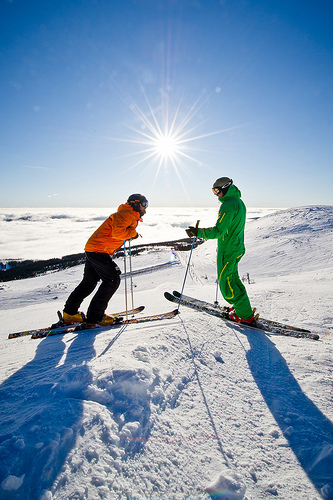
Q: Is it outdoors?
A: Yes, it is outdoors.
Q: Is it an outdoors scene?
A: Yes, it is outdoors.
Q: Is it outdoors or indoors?
A: It is outdoors.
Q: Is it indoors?
A: No, it is outdoors.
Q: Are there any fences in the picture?
A: No, there are no fences.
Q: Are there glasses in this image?
A: No, there are no glasses.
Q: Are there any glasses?
A: No, there are no glasses.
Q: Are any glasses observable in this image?
A: No, there are no glasses.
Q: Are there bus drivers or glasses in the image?
A: No, there are no glasses or bus drivers.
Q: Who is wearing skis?
A: The man is wearing skis.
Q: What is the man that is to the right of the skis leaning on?
A: The man is leaning on the pole.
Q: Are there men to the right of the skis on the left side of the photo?
A: Yes, there is a man to the right of the skis.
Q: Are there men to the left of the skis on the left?
A: No, the man is to the right of the skis.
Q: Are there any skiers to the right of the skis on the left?
A: No, there is a man to the right of the skis.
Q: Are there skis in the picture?
A: Yes, there are skis.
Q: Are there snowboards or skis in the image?
A: Yes, there are skis.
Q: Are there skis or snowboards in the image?
A: Yes, there are skis.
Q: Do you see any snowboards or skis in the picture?
A: Yes, there are skis.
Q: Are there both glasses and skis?
A: No, there are skis but no glasses.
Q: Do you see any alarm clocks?
A: No, there are no alarm clocks.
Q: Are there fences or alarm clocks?
A: No, there are no alarm clocks or fences.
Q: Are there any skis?
A: Yes, there are skis.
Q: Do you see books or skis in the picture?
A: Yes, there are skis.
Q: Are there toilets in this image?
A: No, there are no toilets.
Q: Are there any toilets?
A: No, there are no toilets.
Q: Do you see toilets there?
A: No, there are no toilets.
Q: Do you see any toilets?
A: No, there are no toilets.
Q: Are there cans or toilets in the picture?
A: No, there are no toilets or cans.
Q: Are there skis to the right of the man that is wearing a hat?
A: Yes, there are skis to the right of the man.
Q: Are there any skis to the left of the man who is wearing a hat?
A: No, the skis are to the right of the man.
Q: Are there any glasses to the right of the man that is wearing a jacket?
A: No, there are skis to the right of the man.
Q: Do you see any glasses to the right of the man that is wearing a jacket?
A: No, there are skis to the right of the man.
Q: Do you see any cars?
A: No, there are no cars.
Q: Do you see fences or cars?
A: No, there are no cars or fences.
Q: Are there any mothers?
A: No, there are no mothers.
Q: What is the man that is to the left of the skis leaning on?
A: The man is leaning on the pole.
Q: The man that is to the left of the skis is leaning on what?
A: The man is leaning on the pole.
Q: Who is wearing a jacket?
A: The man is wearing a jacket.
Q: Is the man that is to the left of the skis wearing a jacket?
A: Yes, the man is wearing a jacket.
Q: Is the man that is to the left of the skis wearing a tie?
A: No, the man is wearing a jacket.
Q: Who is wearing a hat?
A: The man is wearing a hat.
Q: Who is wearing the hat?
A: The man is wearing a hat.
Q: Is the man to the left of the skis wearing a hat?
A: Yes, the man is wearing a hat.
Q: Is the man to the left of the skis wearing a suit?
A: No, the man is wearing a hat.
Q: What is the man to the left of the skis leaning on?
A: The man is leaning on the pole.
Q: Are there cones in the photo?
A: No, there are no cones.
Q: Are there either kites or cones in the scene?
A: No, there are no cones or kites.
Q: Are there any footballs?
A: No, there are no footballs.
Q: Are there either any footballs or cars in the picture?
A: No, there are no footballs or cars.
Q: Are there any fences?
A: No, there are no fences.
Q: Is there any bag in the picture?
A: No, there are no bags.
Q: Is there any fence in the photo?
A: No, there are no fences.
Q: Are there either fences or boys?
A: No, there are no fences or boys.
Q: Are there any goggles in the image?
A: Yes, there are goggles.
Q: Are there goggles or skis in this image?
A: Yes, there are goggles.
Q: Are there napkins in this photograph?
A: No, there are no napkins.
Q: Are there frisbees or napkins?
A: No, there are no napkins or frisbees.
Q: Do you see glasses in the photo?
A: No, there are no glasses.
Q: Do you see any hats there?
A: Yes, there is a hat.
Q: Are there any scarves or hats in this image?
A: Yes, there is a hat.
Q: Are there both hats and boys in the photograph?
A: No, there is a hat but no boys.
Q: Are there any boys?
A: No, there are no boys.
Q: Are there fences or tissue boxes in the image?
A: No, there are no fences or tissue boxes.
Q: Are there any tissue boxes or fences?
A: No, there are no fences or tissue boxes.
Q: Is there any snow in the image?
A: Yes, there is snow.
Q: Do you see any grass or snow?
A: Yes, there is snow.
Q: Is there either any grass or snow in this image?
A: Yes, there is snow.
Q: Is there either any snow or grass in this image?
A: Yes, there is snow.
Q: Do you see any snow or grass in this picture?
A: Yes, there is snow.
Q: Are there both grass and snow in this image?
A: No, there is snow but no grass.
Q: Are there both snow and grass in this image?
A: No, there is snow but no grass.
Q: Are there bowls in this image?
A: No, there are no bowls.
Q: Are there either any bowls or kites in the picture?
A: No, there are no bowls or kites.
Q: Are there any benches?
A: No, there are no benches.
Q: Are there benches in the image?
A: No, there are no benches.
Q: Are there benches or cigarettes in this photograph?
A: No, there are no benches or cigarettes.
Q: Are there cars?
A: No, there are no cars.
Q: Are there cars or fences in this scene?
A: No, there are no cars or fences.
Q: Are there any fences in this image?
A: No, there are no fences.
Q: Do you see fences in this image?
A: No, there are no fences.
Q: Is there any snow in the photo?
A: Yes, there is snow.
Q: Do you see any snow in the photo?
A: Yes, there is snow.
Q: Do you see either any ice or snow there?
A: Yes, there is snow.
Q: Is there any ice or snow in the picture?
A: Yes, there is snow.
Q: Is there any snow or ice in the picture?
A: Yes, there is snow.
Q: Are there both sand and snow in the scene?
A: No, there is snow but no sand.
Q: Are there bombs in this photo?
A: No, there are no bombs.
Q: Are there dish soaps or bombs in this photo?
A: No, there are no bombs or dish soaps.